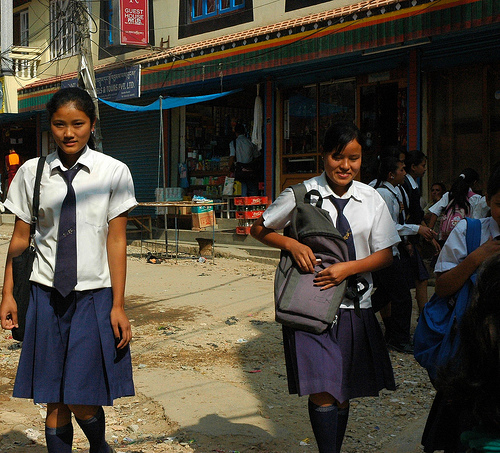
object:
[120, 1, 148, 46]
red sign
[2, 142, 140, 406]
uniform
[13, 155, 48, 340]
bag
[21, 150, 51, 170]
shoulder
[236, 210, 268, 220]
soda rack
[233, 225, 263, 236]
soda rack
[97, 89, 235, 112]
tarp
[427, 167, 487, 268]
kids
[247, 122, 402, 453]
girl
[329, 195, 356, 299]
tie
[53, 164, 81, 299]
tie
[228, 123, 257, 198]
person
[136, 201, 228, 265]
table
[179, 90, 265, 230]
store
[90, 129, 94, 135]
earring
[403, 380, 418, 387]
trash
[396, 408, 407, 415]
rocks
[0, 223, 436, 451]
ground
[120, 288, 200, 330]
dirt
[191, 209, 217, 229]
box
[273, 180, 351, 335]
backpack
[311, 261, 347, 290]
hand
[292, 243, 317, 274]
hands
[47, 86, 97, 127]
hair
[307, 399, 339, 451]
socks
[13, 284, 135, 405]
skirt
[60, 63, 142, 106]
sign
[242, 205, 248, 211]
bottled beverages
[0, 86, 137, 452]
children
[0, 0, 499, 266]
building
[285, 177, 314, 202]
shoulder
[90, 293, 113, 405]
pleat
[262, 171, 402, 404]
outfit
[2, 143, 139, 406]
outfit